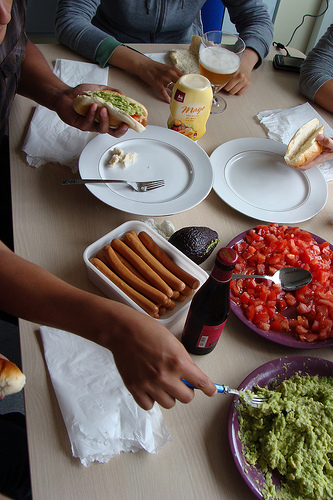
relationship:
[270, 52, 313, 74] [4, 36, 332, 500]
phone on table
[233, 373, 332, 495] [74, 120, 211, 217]
food in plate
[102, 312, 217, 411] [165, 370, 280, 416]
hand holding fork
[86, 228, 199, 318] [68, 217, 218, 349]
franks in dish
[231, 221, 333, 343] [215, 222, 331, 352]
tomato in plate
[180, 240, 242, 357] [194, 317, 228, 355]
bottle with label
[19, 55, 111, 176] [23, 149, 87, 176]
paper with edge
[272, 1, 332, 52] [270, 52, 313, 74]
cable connected to phone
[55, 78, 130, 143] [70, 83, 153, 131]
hand holding hotdog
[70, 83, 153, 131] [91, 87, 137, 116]
hotdog with guacamole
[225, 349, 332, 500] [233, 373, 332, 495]
plate of food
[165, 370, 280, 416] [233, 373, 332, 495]
fork in food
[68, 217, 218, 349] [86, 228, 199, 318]
dish of franks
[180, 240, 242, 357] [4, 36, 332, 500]
bottle on table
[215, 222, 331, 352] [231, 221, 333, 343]
plate holds tomato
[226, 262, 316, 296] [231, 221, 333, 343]
spoon in tomato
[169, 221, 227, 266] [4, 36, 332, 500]
avocado on table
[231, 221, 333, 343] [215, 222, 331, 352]
tomato on plate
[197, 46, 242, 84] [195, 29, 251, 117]
beer in glass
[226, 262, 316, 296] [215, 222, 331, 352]
spoon in plate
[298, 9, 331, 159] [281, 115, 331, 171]
person holding bun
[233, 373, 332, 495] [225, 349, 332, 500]
food on plate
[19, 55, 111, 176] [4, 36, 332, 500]
paper on table